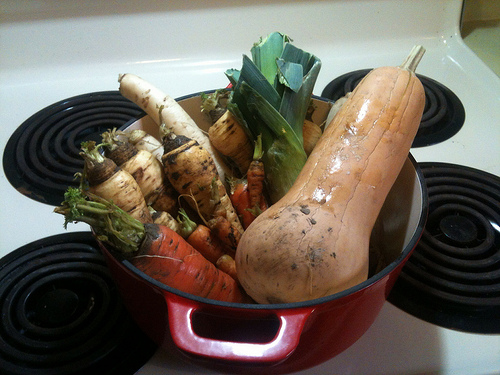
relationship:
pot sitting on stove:
[62, 73, 435, 374] [2, 0, 500, 371]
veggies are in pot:
[47, 20, 442, 315] [62, 73, 435, 374]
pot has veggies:
[62, 73, 435, 374] [47, 20, 442, 315]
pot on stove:
[62, 73, 435, 374] [2, 0, 500, 371]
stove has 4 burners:
[2, 0, 500, 371] [3, 59, 500, 372]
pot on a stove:
[62, 73, 435, 374] [2, 0, 500, 371]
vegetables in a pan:
[47, 20, 442, 315] [62, 73, 435, 374]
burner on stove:
[418, 155, 500, 317] [9, 85, 121, 197]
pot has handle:
[62, 73, 435, 374] [154, 289, 312, 368]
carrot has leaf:
[68, 202, 237, 298] [48, 179, 148, 256]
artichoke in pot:
[299, 104, 331, 140] [62, 73, 435, 374]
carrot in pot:
[68, 202, 237, 298] [62, 73, 435, 374]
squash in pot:
[229, 38, 436, 313] [62, 73, 435, 374]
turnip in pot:
[148, 120, 251, 238] [62, 73, 435, 374]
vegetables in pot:
[47, 20, 442, 315] [62, 73, 435, 374]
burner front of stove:
[418, 155, 500, 317] [2, 0, 500, 371]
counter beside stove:
[461, 3, 499, 61] [2, 0, 500, 371]